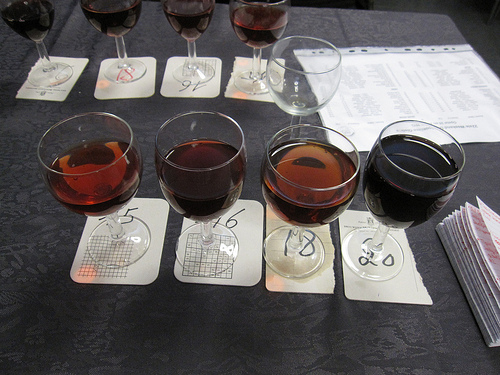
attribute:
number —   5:
[113, 201, 155, 246]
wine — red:
[384, 137, 452, 189]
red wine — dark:
[363, 138, 454, 224]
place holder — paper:
[338, 211, 434, 307]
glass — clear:
[256, 39, 346, 137]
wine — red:
[370, 132, 449, 231]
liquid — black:
[386, 146, 429, 182]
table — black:
[1, 0, 498, 373]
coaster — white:
[336, 206, 433, 306]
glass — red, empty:
[33, 103, 158, 273]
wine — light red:
[48, 141, 138, 217]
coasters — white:
[70, 197, 432, 307]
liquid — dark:
[364, 133, 457, 229]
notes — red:
[457, 206, 498, 269]